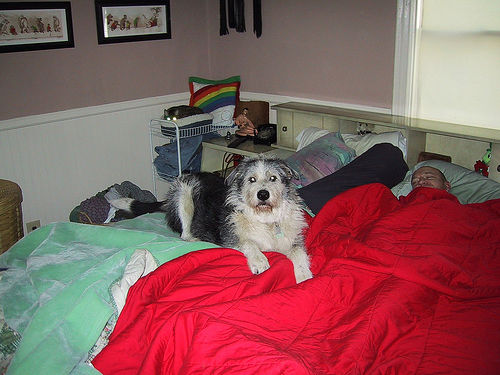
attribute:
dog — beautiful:
[162, 158, 313, 283]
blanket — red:
[90, 182, 497, 373]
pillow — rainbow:
[188, 75, 241, 128]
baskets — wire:
[147, 118, 237, 190]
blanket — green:
[0, 213, 222, 373]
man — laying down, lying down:
[400, 165, 451, 206]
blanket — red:
[313, 194, 474, 374]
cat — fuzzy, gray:
[160, 103, 209, 127]